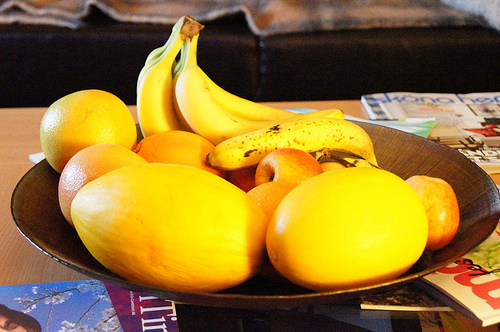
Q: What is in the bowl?
A: Fruit.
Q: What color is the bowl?
A: Brown.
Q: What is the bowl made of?
A: Wood.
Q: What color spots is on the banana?
A: Black.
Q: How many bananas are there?
A: 5.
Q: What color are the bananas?
A: Yellow.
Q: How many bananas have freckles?
A: 1.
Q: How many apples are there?
A: 2.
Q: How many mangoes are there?
A: 2.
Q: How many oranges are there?
A: 2.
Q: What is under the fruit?
A: A shallow bowl.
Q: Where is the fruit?
A: In a bowl.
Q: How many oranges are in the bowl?
A: 4.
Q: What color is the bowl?
A: Brown.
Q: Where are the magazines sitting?
A: On table.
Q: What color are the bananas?
A: Yellow.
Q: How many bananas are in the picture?
A: 5.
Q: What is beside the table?
A: A couch.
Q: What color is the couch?
A: Black.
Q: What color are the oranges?
A: Orange.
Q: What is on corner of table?
A: Several magazines.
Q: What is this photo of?
A: Nice still life.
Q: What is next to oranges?
A: Bananas.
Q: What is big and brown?
A: Bowl.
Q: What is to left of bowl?
A: Magazine.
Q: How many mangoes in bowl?
A: Two.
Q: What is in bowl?
A: Fruit.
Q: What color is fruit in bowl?
A: Yellow.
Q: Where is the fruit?
A: In a bowl.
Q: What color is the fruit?
A: Yellow.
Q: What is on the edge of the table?
A: Magazines.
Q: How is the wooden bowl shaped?
A: Concave.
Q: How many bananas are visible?
A: Two.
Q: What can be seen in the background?
A: Black couch.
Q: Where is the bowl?
A: On a table.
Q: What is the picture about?
A: A fruit bowl.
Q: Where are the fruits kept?
A: In a bowl.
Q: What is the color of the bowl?
A: Brown.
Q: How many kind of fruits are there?
A: Three.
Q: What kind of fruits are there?
A: Apple, banana and oranges.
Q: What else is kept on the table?
A: Magazines.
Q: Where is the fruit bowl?
A: On the coffee table.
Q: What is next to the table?
A: A couch.